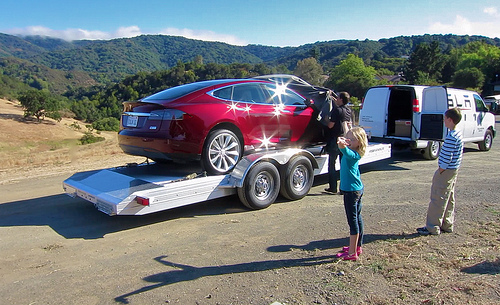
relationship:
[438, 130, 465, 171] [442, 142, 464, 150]
shirt has stripes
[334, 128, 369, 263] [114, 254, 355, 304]
girl casting shadow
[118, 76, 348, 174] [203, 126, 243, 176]
car has wheel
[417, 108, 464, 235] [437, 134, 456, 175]
boy has hand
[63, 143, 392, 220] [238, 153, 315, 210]
trailer has tires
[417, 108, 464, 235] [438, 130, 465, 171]
boy wearing shirt